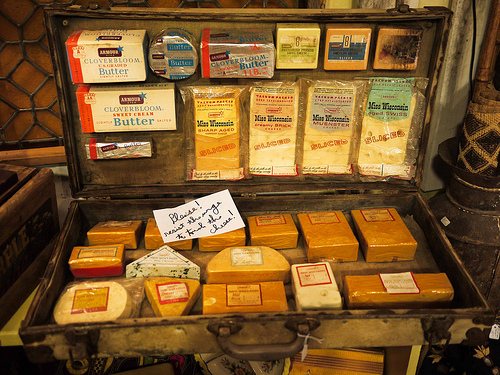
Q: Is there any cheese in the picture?
A: Yes, there is cheese.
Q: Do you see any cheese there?
A: Yes, there is cheese.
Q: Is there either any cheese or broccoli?
A: Yes, there is cheese.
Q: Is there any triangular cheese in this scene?
A: Yes, there is triangular cheese.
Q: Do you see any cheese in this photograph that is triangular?
A: Yes, there is cheese that is triangular.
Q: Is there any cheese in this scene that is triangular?
A: Yes, there is cheese that is triangular.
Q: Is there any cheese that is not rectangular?
A: Yes, there is triangular cheese.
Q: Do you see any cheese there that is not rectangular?
A: Yes, there is triangular cheese.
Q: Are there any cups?
A: No, there are no cups.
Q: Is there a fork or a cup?
A: No, there are no cups or forks.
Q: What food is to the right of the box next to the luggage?
A: The food is cheese.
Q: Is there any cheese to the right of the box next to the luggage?
A: Yes, there is cheese to the right of the box.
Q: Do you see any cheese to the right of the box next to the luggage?
A: Yes, there is cheese to the right of the box.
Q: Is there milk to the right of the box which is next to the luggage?
A: No, there is cheese to the right of the box.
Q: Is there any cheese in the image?
A: Yes, there is cheese.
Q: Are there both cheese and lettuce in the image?
A: No, there is cheese but no lettuce.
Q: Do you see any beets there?
A: No, there are no beets.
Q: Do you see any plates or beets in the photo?
A: No, there are no beets or plates.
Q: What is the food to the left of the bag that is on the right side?
A: The food is cheese.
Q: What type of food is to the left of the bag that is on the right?
A: The food is cheese.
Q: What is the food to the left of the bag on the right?
A: The food is cheese.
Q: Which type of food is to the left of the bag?
A: The food is cheese.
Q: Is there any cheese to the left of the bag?
A: Yes, there is cheese to the left of the bag.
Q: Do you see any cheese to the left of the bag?
A: Yes, there is cheese to the left of the bag.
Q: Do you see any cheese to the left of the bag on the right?
A: Yes, there is cheese to the left of the bag.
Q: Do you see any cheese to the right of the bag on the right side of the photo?
A: No, the cheese is to the left of the bag.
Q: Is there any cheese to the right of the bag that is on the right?
A: No, the cheese is to the left of the bag.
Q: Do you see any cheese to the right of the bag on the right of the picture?
A: No, the cheese is to the left of the bag.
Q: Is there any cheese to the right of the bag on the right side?
A: No, the cheese is to the left of the bag.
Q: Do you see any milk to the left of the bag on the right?
A: No, there is cheese to the left of the bag.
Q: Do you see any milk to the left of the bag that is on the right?
A: No, there is cheese to the left of the bag.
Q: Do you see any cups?
A: No, there are no cups.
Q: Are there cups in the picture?
A: No, there are no cups.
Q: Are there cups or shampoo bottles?
A: No, there are no cups or shampoo bottles.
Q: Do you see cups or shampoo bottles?
A: No, there are no cups or shampoo bottles.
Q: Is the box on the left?
A: Yes, the box is on the left of the image.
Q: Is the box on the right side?
A: No, the box is on the left of the image.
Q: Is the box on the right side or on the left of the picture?
A: The box is on the left of the image.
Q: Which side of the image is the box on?
A: The box is on the left of the image.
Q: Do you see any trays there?
A: No, there are no trays.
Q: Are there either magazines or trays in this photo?
A: No, there are no trays or magazines.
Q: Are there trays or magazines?
A: No, there are no trays or magazines.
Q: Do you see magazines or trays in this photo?
A: No, there are no trays or magazines.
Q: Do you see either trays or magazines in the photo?
A: No, there are no trays or magazines.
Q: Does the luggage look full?
A: Yes, the luggage is full.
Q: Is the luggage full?
A: Yes, the luggage is full.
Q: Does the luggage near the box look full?
A: Yes, the luggage is full.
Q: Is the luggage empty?
A: No, the luggage is full.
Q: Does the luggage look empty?
A: No, the luggage is full.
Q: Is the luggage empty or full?
A: The luggage is full.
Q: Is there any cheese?
A: Yes, there is cheese.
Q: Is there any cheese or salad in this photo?
A: Yes, there is cheese.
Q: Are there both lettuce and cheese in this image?
A: No, there is cheese but no lettuce.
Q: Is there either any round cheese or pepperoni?
A: Yes, there is round cheese.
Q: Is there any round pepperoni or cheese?
A: Yes, there is round cheese.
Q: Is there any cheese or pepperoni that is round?
A: Yes, the cheese is round.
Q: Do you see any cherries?
A: No, there are no cherries.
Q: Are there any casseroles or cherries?
A: No, there are no cherries or casseroles.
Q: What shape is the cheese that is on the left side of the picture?
A: The cheese is round.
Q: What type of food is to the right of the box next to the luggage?
A: The food is cheese.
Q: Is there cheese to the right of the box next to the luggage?
A: Yes, there is cheese to the right of the box.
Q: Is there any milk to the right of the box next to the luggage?
A: No, there is cheese to the right of the box.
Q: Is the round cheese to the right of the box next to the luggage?
A: Yes, the cheese is to the right of the box.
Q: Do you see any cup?
A: No, there are no cups.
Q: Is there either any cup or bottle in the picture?
A: No, there are no cups or bottles.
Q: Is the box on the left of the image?
A: Yes, the box is on the left of the image.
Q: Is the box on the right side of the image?
A: No, the box is on the left of the image.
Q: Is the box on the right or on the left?
A: The box is on the left of the image.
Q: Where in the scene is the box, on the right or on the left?
A: The box is on the left of the image.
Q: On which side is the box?
A: The box is on the left of the image.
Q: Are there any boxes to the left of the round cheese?
A: Yes, there is a box to the left of the cheese.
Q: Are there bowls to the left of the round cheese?
A: No, there is a box to the left of the cheese.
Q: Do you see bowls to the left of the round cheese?
A: No, there is a box to the left of the cheese.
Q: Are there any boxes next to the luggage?
A: Yes, there is a box next to the luggage.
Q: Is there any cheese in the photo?
A: Yes, there is cheese.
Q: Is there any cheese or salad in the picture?
A: Yes, there is cheese.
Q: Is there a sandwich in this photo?
A: No, there are no sandwiches.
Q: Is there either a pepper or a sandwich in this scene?
A: No, there are no sandwiches or peppers.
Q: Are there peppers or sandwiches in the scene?
A: No, there are no sandwiches or peppers.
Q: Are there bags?
A: Yes, there is a bag.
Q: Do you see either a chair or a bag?
A: Yes, there is a bag.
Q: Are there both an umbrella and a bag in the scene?
A: No, there is a bag but no umbrellas.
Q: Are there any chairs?
A: No, there are no chairs.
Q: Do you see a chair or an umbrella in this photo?
A: No, there are no chairs or umbrellas.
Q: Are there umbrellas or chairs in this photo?
A: No, there are no chairs or umbrellas.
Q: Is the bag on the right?
A: Yes, the bag is on the right of the image.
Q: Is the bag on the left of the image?
A: No, the bag is on the right of the image.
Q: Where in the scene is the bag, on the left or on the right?
A: The bag is on the right of the image.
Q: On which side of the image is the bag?
A: The bag is on the right of the image.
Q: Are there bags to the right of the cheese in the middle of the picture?
A: Yes, there is a bag to the right of the cheese.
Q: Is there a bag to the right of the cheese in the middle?
A: Yes, there is a bag to the right of the cheese.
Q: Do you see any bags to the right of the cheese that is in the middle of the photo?
A: Yes, there is a bag to the right of the cheese.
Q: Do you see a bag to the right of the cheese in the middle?
A: Yes, there is a bag to the right of the cheese.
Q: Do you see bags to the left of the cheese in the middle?
A: No, the bag is to the right of the cheese.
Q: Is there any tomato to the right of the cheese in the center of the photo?
A: No, there is a bag to the right of the cheese.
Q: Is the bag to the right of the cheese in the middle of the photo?
A: Yes, the bag is to the right of the cheese.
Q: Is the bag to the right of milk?
A: No, the bag is to the right of the cheese.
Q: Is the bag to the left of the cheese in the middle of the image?
A: No, the bag is to the right of the cheese.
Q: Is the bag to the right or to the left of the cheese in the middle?
A: The bag is to the right of the cheese.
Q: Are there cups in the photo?
A: No, there are no cups.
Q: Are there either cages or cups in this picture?
A: No, there are no cups or cages.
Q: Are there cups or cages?
A: No, there are no cups or cages.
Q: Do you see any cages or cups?
A: No, there are no cups or cages.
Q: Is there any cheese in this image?
A: Yes, there is cheese.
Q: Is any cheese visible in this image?
A: Yes, there is cheese.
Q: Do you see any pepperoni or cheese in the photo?
A: Yes, there is cheese.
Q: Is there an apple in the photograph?
A: No, there are no apples.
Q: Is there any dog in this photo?
A: No, there are no dogs.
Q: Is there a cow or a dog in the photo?
A: No, there are no dogs or cows.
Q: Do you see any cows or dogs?
A: No, there are no dogs or cows.